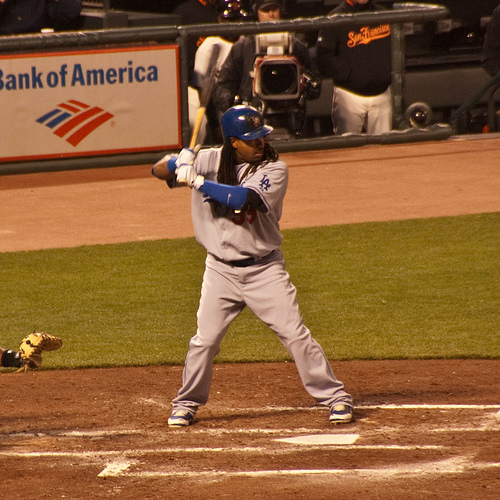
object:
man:
[148, 103, 356, 431]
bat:
[186, 42, 225, 154]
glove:
[16, 331, 64, 372]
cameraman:
[212, 0, 323, 141]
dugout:
[0, 0, 497, 177]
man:
[315, 0, 396, 137]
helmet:
[219, 103, 274, 144]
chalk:
[133, 394, 500, 414]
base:
[267, 431, 362, 446]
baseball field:
[0, 130, 500, 500]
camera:
[231, 30, 323, 143]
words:
[258, 178, 269, 191]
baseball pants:
[166, 249, 357, 413]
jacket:
[315, 2, 395, 97]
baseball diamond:
[2, 354, 500, 500]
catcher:
[0, 331, 65, 375]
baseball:
[0, 0, 500, 500]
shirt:
[164, 145, 290, 263]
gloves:
[173, 162, 206, 191]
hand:
[174, 162, 206, 192]